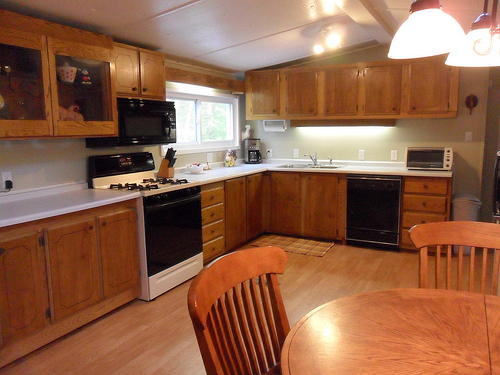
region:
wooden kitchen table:
[283, 282, 495, 372]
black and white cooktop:
[82, 150, 202, 190]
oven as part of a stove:
[141, 194, 201, 276]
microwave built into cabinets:
[114, 95, 179, 143]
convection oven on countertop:
[400, 145, 456, 172]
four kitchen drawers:
[198, 186, 225, 263]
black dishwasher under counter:
[341, 170, 396, 246]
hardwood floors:
[300, 255, 415, 295]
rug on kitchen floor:
[252, 231, 327, 257]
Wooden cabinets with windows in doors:
[1, 45, 111, 133]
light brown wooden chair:
[145, 222, 307, 373]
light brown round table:
[269, 242, 499, 373]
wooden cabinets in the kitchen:
[0, 195, 162, 365]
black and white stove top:
[80, 138, 204, 313]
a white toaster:
[390, 130, 477, 184]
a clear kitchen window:
[147, 82, 244, 161]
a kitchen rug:
[240, 215, 332, 270]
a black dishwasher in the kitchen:
[337, 166, 408, 257]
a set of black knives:
[156, 143, 183, 188]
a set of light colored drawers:
[192, 181, 228, 265]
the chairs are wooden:
[127, 213, 467, 353]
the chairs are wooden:
[238, 246, 409, 371]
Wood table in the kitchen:
[279, 282, 499, 372]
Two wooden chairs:
[158, 208, 496, 366]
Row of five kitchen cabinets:
[241, 57, 467, 134]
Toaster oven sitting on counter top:
[332, 146, 461, 177]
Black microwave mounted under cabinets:
[84, 92, 181, 149]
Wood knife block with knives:
[154, 145, 181, 182]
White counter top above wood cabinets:
[2, 174, 134, 277]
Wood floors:
[113, 300, 203, 372]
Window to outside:
[156, 77, 247, 157]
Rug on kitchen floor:
[250, 228, 336, 274]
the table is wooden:
[201, 257, 361, 366]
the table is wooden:
[217, 220, 459, 372]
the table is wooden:
[253, 262, 412, 369]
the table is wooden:
[387, 290, 494, 373]